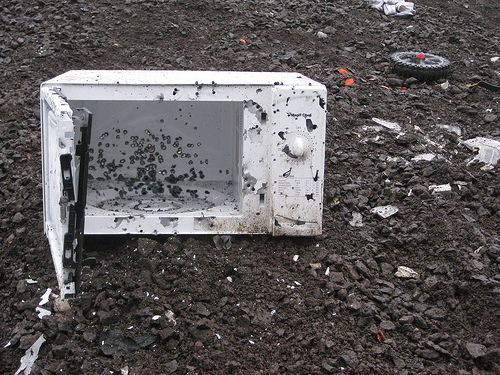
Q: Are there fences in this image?
A: No, there are no fences.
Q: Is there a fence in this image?
A: No, there are no fences.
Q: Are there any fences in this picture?
A: No, there are no fences.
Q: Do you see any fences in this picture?
A: No, there are no fences.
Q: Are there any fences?
A: No, there are no fences.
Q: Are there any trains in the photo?
A: No, there are no trains.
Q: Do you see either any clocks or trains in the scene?
A: No, there are no trains or clocks.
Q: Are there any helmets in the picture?
A: No, there are no helmets.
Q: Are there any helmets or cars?
A: No, there are no helmets or cars.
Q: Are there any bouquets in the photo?
A: No, there are no bouquets.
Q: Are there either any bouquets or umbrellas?
A: No, there are no bouquets or umbrellas.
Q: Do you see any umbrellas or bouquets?
A: No, there are no bouquets or umbrellas.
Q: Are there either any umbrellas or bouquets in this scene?
A: No, there are no bouquets or umbrellas.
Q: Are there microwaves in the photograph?
A: Yes, there is a microwave.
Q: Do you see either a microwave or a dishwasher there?
A: Yes, there is a microwave.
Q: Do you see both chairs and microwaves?
A: No, there is a microwave but no chairs.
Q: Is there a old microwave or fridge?
A: Yes, there is an old microwave.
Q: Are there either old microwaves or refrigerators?
A: Yes, there is an old microwave.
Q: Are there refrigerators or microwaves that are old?
A: Yes, the microwave is old.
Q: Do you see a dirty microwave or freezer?
A: Yes, there is a dirty microwave.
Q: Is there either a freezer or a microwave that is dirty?
A: Yes, the microwave is dirty.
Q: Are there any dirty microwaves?
A: Yes, there is a dirty microwave.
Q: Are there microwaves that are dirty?
A: Yes, there is a microwave that is dirty.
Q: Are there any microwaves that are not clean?
A: Yes, there is a dirty microwave.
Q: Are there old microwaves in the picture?
A: Yes, there is an old microwave.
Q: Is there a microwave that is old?
A: Yes, there is a microwave that is old.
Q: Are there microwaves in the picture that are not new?
A: Yes, there is a old microwave.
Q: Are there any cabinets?
A: No, there are no cabinets.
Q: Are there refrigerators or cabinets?
A: No, there are no cabinets or refrigerators.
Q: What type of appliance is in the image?
A: The appliance is a microwave.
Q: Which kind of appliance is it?
A: The appliance is a microwave.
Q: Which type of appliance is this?
A: This is a microwave.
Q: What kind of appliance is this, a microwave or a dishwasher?
A: This is a microwave.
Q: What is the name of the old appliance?
A: The appliance is a microwave.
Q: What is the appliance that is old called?
A: The appliance is a microwave.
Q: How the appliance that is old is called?
A: The appliance is a microwave.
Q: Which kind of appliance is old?
A: The appliance is a microwave.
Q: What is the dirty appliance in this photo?
A: The appliance is a microwave.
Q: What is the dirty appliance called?
A: The appliance is a microwave.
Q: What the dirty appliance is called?
A: The appliance is a microwave.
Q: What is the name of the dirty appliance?
A: The appliance is a microwave.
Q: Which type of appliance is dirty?
A: The appliance is a microwave.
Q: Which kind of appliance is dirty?
A: The appliance is a microwave.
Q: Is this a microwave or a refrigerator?
A: This is a microwave.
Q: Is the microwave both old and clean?
A: No, the microwave is old but dirty.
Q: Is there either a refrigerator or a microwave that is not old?
A: No, there is a microwave but it is old.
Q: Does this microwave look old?
A: Yes, the microwave is old.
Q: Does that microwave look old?
A: Yes, the microwave is old.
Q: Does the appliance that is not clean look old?
A: Yes, the microwave is old.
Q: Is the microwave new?
A: No, the microwave is old.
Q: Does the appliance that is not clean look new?
A: No, the microwave is old.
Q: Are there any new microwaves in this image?
A: No, there is a microwave but it is old.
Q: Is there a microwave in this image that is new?
A: No, there is a microwave but it is old.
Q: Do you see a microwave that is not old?
A: No, there is a microwave but it is old.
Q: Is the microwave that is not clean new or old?
A: The microwave is old.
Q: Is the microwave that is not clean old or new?
A: The microwave is old.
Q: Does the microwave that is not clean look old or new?
A: The microwave is old.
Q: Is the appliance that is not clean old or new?
A: The microwave is old.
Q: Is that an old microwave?
A: Yes, that is an old microwave.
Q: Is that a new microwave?
A: No, that is an old microwave.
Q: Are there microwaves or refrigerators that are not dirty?
A: No, there is a microwave but it is dirty.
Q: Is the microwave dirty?
A: Yes, the microwave is dirty.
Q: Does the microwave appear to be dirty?
A: Yes, the microwave is dirty.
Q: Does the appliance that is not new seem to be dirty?
A: Yes, the microwave is dirty.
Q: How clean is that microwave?
A: The microwave is dirty.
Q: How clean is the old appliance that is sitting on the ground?
A: The microwave is dirty.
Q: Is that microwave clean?
A: No, the microwave is dirty.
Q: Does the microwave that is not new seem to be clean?
A: No, the microwave is dirty.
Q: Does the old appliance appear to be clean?
A: No, the microwave is dirty.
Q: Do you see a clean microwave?
A: No, there is a microwave but it is dirty.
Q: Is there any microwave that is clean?
A: No, there is a microwave but it is dirty.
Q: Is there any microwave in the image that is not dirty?
A: No, there is a microwave but it is dirty.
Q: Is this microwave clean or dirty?
A: The microwave is dirty.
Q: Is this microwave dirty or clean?
A: The microwave is dirty.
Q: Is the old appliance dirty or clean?
A: The microwave is dirty.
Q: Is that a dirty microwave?
A: Yes, that is a dirty microwave.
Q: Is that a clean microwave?
A: No, that is a dirty microwave.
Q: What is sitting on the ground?
A: The microwave is sitting on the ground.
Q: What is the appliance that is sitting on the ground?
A: The appliance is a microwave.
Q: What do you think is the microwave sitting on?
A: The microwave is sitting on the ground.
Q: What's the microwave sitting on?
A: The microwave is sitting on the ground.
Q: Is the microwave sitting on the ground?
A: Yes, the microwave is sitting on the ground.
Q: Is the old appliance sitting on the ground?
A: Yes, the microwave is sitting on the ground.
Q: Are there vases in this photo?
A: No, there are no vases.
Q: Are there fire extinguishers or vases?
A: No, there are no vases or fire extinguishers.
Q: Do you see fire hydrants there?
A: No, there are no fire hydrants.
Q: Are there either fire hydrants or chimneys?
A: No, there are no fire hydrants or chimneys.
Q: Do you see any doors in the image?
A: Yes, there is a door.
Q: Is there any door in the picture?
A: Yes, there is a door.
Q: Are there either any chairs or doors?
A: Yes, there is a door.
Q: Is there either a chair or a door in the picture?
A: Yes, there is a door.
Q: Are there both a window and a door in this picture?
A: No, there is a door but no windows.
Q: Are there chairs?
A: No, there are no chairs.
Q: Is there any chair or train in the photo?
A: No, there are no chairs or trains.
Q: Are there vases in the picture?
A: No, there are no vases.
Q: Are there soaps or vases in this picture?
A: No, there are no vases or soaps.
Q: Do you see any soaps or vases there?
A: No, there are no vases or soaps.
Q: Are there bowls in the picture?
A: No, there are no bowls.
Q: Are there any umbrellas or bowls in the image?
A: No, there are no bowls or umbrellas.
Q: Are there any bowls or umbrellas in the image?
A: No, there are no bowls or umbrellas.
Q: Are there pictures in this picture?
A: No, there are no pictures.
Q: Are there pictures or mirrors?
A: No, there are no pictures or mirrors.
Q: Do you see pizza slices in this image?
A: No, there are no pizza slices.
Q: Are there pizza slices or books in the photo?
A: No, there are no pizza slices or books.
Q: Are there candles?
A: No, there are no candles.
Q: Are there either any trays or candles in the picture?
A: No, there are no candles or trays.